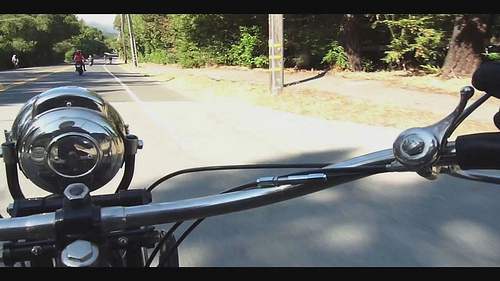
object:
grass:
[289, 92, 412, 128]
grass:
[172, 72, 256, 100]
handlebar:
[0, 130, 499, 244]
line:
[101, 56, 172, 116]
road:
[0, 57, 496, 277]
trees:
[57, 30, 103, 67]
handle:
[454, 128, 499, 171]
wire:
[159, 163, 260, 176]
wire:
[221, 177, 261, 192]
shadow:
[132, 147, 499, 265]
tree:
[367, 8, 497, 83]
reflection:
[38, 118, 92, 167]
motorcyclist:
[39, 120, 98, 178]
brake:
[395, 85, 472, 167]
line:
[102, 61, 142, 112]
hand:
[472, 44, 497, 104]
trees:
[234, 12, 265, 71]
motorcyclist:
[73, 50, 87, 73]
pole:
[269, 13, 289, 93]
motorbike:
[74, 58, 87, 77]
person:
[12, 52, 20, 70]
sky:
[77, 14, 125, 27]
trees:
[165, 14, 202, 70]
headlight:
[2, 83, 138, 202]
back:
[16, 106, 127, 193]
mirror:
[10, 107, 133, 190]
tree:
[0, 13, 40, 55]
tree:
[130, 8, 185, 61]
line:
[268, 38, 286, 55]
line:
[0, 66, 77, 100]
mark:
[269, 41, 283, 49]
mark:
[268, 67, 281, 71]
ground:
[0, 59, 497, 269]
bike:
[1, 54, 498, 266]